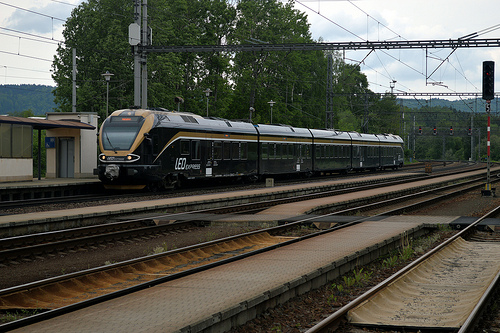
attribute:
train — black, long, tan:
[89, 106, 414, 191]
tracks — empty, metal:
[191, 181, 490, 322]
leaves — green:
[74, 10, 311, 79]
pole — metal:
[129, 12, 144, 110]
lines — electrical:
[10, 5, 72, 77]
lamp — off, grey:
[97, 65, 120, 114]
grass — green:
[395, 237, 414, 261]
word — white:
[175, 153, 189, 173]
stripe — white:
[144, 131, 402, 160]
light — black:
[483, 56, 493, 108]